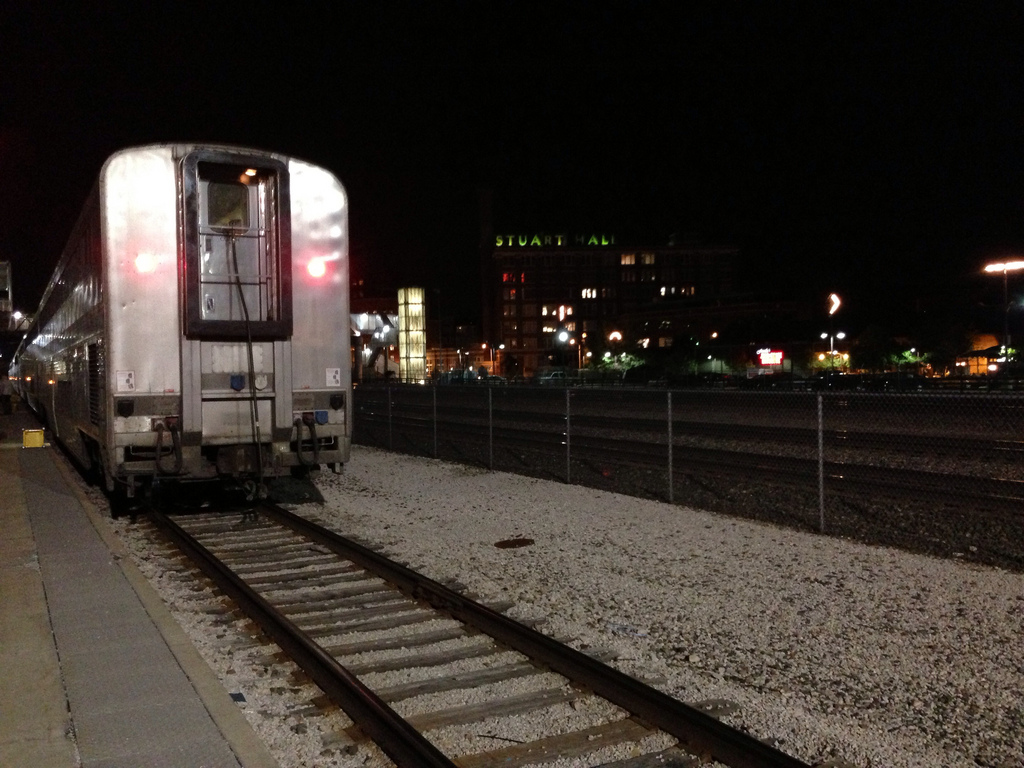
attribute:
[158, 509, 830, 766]
train track — active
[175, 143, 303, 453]
back door — train's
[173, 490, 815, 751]
tracks — brown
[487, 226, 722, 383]
building — large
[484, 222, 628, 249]
letter — green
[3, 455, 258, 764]
floor — concrete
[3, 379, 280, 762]
walkway — concrete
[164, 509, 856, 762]
track — train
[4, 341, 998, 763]
station — train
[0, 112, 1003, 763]
station — train